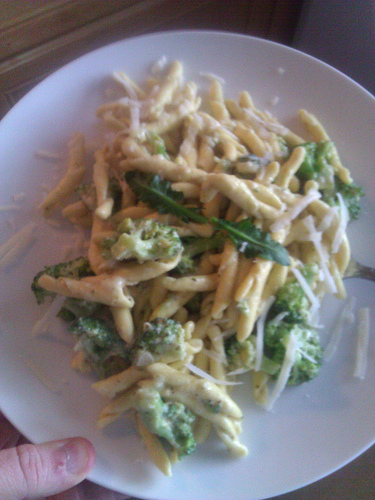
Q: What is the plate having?
A: Food.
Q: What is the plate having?
A: Noodles.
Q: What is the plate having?
A: Noodles.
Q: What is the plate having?
A: Noodles.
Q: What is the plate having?
A: Noodles.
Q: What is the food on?
A: A white plate.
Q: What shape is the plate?
A: Round.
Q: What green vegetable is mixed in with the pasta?
A: Broccoli.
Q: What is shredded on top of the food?
A: Cheese.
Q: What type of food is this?
A: Pasta.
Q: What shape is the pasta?
A: Tubular.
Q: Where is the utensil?
A: On the right side under the pasta.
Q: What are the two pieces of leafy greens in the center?
A: Garnishes.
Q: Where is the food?
A: On the white plate.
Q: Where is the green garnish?
A: On top of the food.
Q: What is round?
A: Plate.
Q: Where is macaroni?
A: On a plate.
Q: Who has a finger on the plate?
A: A person.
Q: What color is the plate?
A: White.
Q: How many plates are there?
A: One.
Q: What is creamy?
A: The macaroni.